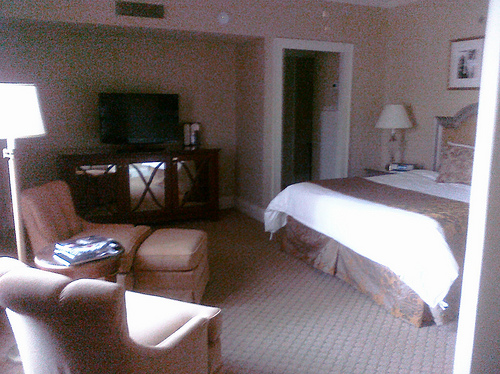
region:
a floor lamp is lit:
[0, 77, 45, 264]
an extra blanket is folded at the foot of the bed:
[260, 171, 459, 309]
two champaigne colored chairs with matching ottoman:
[0, 177, 225, 372]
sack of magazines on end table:
[41, 230, 125, 267]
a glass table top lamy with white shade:
[371, 92, 411, 169]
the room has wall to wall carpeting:
[1, 192, 463, 373]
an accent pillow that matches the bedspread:
[423, 124, 494, 207]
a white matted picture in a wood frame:
[444, 29, 486, 97]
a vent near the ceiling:
[108, 2, 169, 22]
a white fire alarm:
[213, 5, 238, 31]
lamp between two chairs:
[3, 72, 53, 279]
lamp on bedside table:
[373, 102, 411, 167]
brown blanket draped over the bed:
[305, 152, 473, 265]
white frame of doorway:
[263, 39, 355, 212]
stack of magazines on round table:
[55, 230, 112, 263]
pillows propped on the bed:
[434, 134, 466, 184]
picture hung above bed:
[442, 31, 484, 90]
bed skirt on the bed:
[278, 210, 423, 319]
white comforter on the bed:
[264, 161, 466, 308]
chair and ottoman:
[22, 179, 213, 297]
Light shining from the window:
[133, 295, 173, 335]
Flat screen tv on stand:
[88, 82, 217, 164]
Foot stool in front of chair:
[134, 211, 224, 295]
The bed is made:
[308, 148, 497, 299]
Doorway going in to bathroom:
[273, 32, 377, 199]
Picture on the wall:
[429, 22, 497, 106]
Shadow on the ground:
[199, 245, 230, 270]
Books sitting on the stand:
[178, 110, 218, 160]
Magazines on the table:
[58, 230, 127, 274]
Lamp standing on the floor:
[4, 76, 55, 195]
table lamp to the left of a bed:
[375, 102, 416, 170]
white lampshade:
[371, 101, 412, 131]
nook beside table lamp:
[385, 160, 414, 173]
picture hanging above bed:
[446, 35, 488, 91]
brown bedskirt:
[283, 215, 431, 325]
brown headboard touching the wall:
[430, 102, 482, 169]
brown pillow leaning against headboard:
[435, 142, 480, 185]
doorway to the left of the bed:
[268, 39, 349, 198]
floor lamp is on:
[0, 80, 47, 262]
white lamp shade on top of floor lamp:
[1, 83, 43, 138]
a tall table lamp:
[372, 100, 419, 171]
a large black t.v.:
[90, 85, 191, 144]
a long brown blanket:
[304, 172, 469, 264]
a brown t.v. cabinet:
[55, 150, 225, 219]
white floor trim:
[230, 192, 265, 220]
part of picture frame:
[445, 38, 481, 93]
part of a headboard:
[427, 99, 475, 169]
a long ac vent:
[112, 0, 169, 19]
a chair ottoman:
[140, 222, 213, 294]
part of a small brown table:
[28, 248, 118, 283]